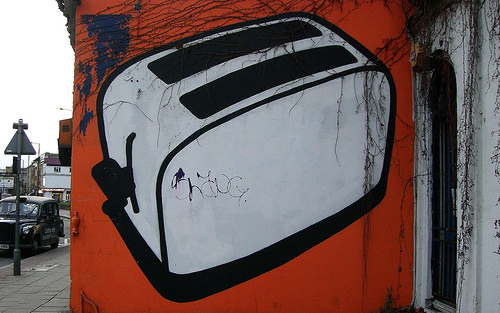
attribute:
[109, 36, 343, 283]
art — street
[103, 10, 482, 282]
wall — painted, reddish, red, cracking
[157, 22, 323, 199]
toaster — painted, clip art, white, black, here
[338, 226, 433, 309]
background — orange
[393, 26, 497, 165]
vines — growing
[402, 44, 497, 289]
window — arched, here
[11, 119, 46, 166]
sign — here, street, triangular, shaped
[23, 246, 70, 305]
sidewalk — squared, gray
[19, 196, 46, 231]
car — old, dark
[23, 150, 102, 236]
buildngs — down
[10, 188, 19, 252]
signpost — grey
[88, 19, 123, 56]
background — blue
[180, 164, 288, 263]
letters — graffiti